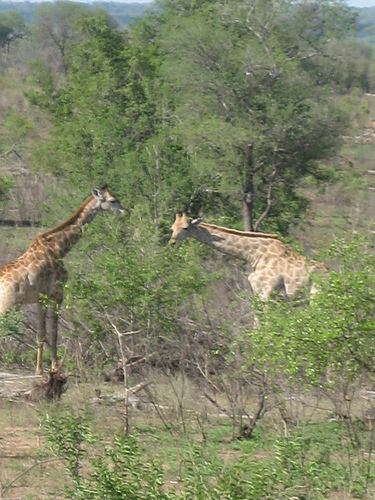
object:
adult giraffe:
[0, 182, 131, 378]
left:
[13, 9, 160, 420]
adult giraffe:
[167, 208, 369, 410]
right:
[172, 9, 375, 405]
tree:
[162, 0, 353, 235]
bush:
[137, 230, 298, 445]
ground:
[0, 367, 375, 500]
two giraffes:
[0, 182, 341, 377]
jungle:
[0, 1, 375, 496]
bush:
[213, 226, 375, 427]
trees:
[147, 0, 374, 349]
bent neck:
[195, 218, 254, 268]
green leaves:
[96, 40, 110, 70]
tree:
[18, 1, 202, 324]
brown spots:
[25, 253, 36, 263]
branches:
[103, 309, 130, 436]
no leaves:
[123, 325, 177, 381]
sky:
[0, 0, 375, 12]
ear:
[90, 186, 104, 200]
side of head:
[91, 187, 131, 220]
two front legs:
[34, 278, 65, 378]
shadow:
[173, 219, 226, 253]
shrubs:
[28, 406, 188, 499]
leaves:
[283, 361, 293, 377]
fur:
[28, 183, 108, 250]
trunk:
[30, 367, 68, 403]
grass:
[0, 380, 375, 497]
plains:
[0, 53, 375, 500]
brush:
[38, 202, 225, 436]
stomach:
[11, 274, 55, 305]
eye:
[108, 199, 118, 204]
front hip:
[303, 255, 334, 290]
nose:
[121, 207, 130, 215]